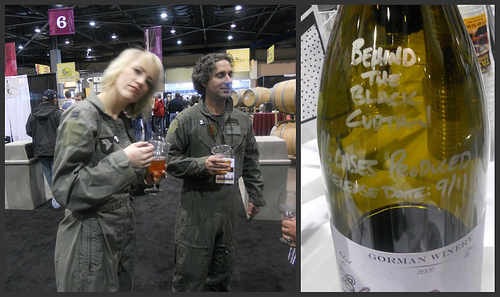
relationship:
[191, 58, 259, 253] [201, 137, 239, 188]
man holding empty glass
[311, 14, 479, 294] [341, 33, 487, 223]
wine bottle with silver writing